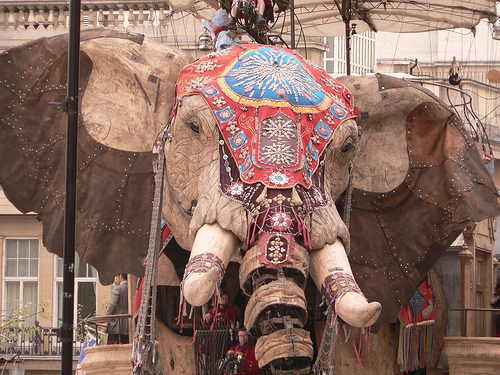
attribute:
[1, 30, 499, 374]
elephant — large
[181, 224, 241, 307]
tusk — ivory, white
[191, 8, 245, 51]
person — standing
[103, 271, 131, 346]
man — standing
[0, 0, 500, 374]
building — tan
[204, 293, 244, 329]
man — watching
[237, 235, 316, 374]
trunk — made of cloth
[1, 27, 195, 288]
ear — made from fabric, brown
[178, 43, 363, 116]
forehead — made from fabric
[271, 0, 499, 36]
sail — large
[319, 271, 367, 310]
decoration — brown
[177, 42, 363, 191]
hat — red, blue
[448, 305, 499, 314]
railing — silver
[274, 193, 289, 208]
diamond — brown, white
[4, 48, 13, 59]
dot — white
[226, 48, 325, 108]
circle — blue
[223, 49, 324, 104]
design — white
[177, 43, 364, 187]
cloth — decorative, red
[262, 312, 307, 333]
part — exposed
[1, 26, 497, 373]
statue — elephant